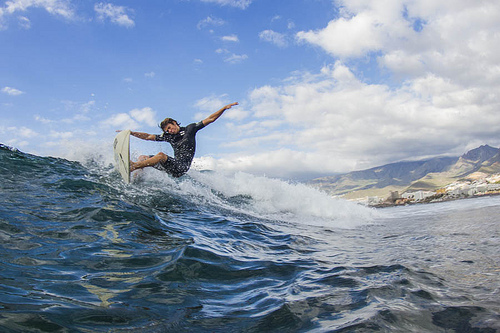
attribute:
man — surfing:
[93, 54, 242, 197]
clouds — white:
[226, 7, 498, 151]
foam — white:
[74, 144, 427, 231]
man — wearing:
[112, 101, 235, 174]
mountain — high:
[364, 146, 498, 198]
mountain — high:
[300, 155, 453, 193]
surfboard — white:
[109, 127, 134, 187]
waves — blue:
[0, 142, 392, 329]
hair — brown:
[158, 119, 176, 125]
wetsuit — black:
[154, 129, 201, 178]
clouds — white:
[294, 9, 472, 132]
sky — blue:
[9, 6, 346, 140]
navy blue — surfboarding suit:
[115, 120, 252, 182]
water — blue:
[0, 153, 500, 330]